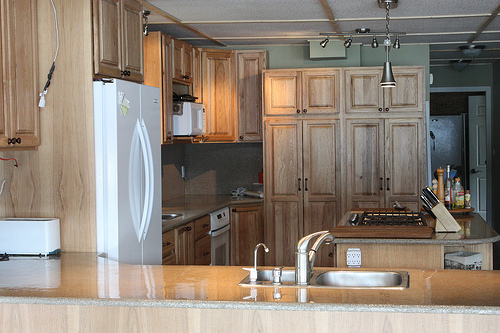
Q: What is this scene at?
A: Kitchen.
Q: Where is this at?
A: Kitchen.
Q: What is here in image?
A: Silver sink.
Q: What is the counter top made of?
A: Marble.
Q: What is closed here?
A: Refrigerator.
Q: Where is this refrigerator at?
A: Kitchen.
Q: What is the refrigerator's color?
A: White.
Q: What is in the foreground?
A: Sink.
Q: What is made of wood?
A: The cabinets.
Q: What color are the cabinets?
A: Brown.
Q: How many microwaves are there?
A: One.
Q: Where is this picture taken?
A: In a kitchen.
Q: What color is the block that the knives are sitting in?
A: Brown.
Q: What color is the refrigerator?
A: White.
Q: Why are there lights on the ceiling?
A: So the home owners will be able to see in the home.